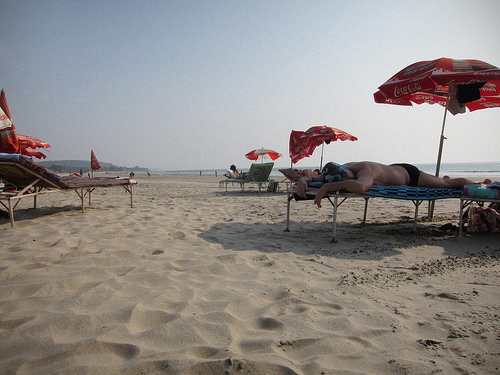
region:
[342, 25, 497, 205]
A large red umbrella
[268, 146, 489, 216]
A person sun bathing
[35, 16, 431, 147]
Pretty blue clear skies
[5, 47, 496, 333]
A beach full of people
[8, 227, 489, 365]
A bunch of sand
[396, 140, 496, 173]
The blue ocean water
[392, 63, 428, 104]
The coca-cola logo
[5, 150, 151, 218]
Brown wooden lawn chairs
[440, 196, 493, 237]
A large beach bag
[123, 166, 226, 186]
Beach goers in the distance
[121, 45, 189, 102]
sky above the ground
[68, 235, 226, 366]
prints in the sand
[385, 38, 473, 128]
umbrella above the ground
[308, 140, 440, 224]
person laying face down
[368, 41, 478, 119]
umbrella with coke logo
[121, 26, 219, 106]
sky with no clouds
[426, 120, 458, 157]
pole on the umbrella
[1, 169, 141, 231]
recliner on the sand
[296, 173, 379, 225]
arm of the person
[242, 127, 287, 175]
umbrella in the background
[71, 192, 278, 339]
the sand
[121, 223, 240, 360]
the sand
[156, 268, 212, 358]
the sand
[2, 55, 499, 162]
red and white umbrellas dot the beach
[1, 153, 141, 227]
an empty beach chair at the beach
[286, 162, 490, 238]
a man lying on his stomach on a beach chair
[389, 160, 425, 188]
the man has a black bathing suit on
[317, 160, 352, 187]
a hat is on a man's head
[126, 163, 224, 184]
people are walking on the beach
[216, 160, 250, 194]
a woman is on a cell phone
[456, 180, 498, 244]
a table is next to the beach chair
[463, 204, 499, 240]
a bag is under the table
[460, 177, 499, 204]
items are on top of the table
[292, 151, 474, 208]
the man is sun bathing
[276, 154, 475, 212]
the man is lying down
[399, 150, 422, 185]
the bathing suit is black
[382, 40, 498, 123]
the umbrella is open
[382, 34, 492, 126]
the umbrella is red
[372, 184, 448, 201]
the towel is blue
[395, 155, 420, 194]
the man is wearing a bathing suit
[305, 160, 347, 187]
the man is wearing a bandana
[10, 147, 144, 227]
the chair is empty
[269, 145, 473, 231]
the man is at the beach